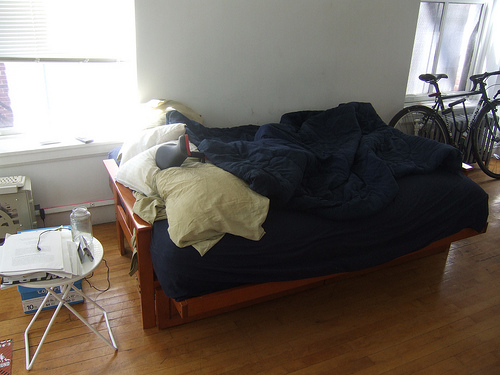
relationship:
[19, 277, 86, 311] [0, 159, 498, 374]
box on floor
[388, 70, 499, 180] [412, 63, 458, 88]
bicycle has seat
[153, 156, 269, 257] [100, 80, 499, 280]
pillow on bed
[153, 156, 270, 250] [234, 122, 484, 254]
pillow on bed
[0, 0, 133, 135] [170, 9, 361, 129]
window in wall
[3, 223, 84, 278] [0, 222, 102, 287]
papers on tabletop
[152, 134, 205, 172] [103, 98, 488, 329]
bike seat o an bed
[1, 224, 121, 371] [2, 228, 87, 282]
small table with a bunch of papers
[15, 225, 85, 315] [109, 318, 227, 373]
box on floor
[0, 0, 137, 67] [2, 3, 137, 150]
blind at window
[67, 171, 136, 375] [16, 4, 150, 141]
sunlight coming through window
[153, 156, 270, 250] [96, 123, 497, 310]
pillow on a bed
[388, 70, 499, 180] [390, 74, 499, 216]
bicycle parked inside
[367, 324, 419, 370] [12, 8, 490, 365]
wooden flooring in a bedroom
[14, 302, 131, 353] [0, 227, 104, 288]
metal bottom on a tabletop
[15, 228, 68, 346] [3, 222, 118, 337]
stack of paper on table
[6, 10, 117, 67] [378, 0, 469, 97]
white blinds covering a window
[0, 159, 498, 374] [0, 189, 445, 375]
floor of a bedroom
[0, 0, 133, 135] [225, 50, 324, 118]
window in  a wall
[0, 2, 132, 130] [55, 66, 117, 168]
window blinds closed but pulled half way up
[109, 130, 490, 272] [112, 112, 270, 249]
mattress with navy blue sheets and comforter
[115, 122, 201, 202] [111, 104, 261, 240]
pillow cases are on pillows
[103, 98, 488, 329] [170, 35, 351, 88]
bed is beside brick wall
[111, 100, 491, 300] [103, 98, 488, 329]
comforter is on bed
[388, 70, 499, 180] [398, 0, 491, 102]
bicycle is beside window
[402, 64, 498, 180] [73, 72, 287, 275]
bicycle is beside pillow